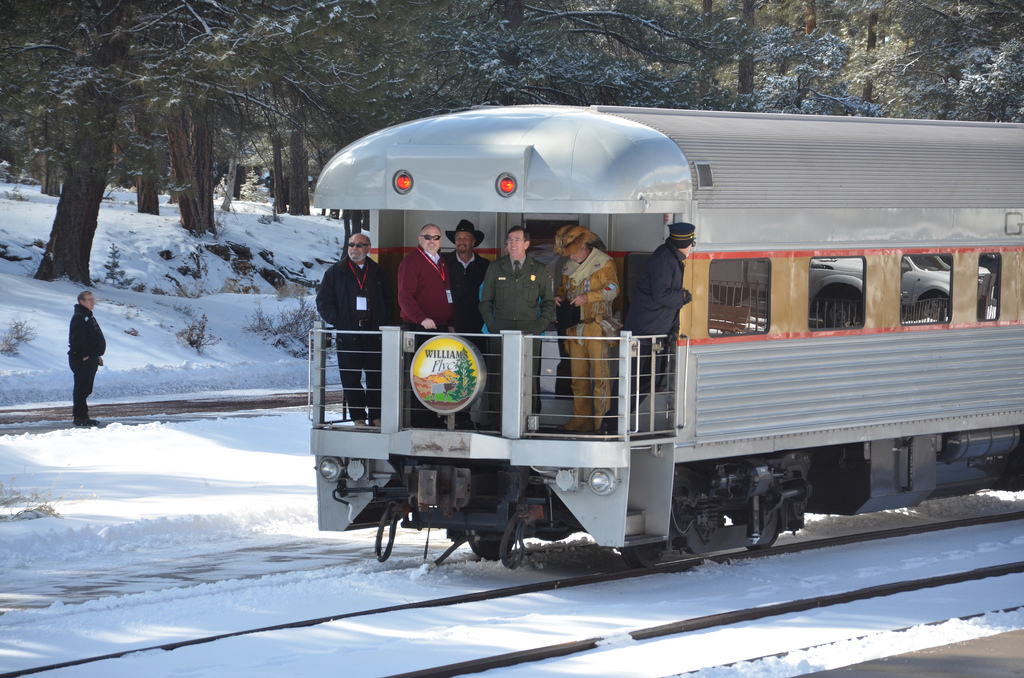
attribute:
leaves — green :
[15, 2, 183, 305]